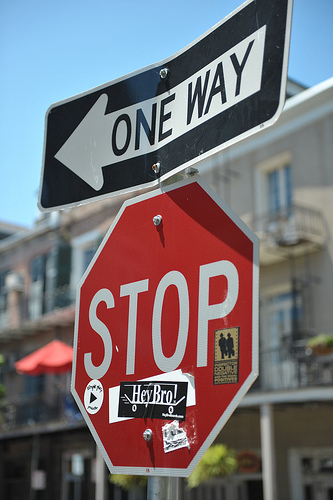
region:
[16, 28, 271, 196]
white arrow on the sign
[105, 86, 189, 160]
word on the sign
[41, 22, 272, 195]
white arrow on black background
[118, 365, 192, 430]
sticker on the sign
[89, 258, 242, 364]
white letters on sign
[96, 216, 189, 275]
light hitting the sign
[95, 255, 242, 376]
red and white sign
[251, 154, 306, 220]
window behind the sign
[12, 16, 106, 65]
blue sky above the building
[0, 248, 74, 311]
blurry background of the photo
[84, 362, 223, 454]
bumper stickers on the stop sign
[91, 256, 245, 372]
STOP written in white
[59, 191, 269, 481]
stop sign is red and white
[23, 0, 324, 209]
street sign is black and white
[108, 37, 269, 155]
ONE WAY written in black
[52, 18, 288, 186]
white arrow on street sign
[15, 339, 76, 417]
red umbrella on a balcony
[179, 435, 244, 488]
hanging flowers on the street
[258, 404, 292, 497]
white pole next to hanging basket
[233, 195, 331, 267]
balcony on the building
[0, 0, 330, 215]
Black and white one way sign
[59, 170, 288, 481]
Red and white stop sign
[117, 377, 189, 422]
Black and white sticker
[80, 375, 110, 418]
Black and white circle sticker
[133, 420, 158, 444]
silver bolt on stop sign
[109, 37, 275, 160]
Black lettering on sign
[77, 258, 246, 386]
White lettering on sign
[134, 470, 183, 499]
Silver pole to hold signs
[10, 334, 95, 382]
Red umbrella on the balcony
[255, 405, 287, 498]
White support beams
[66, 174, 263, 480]
A red and white stop sign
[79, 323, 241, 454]
Stickers on the stop sign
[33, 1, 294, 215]
A black and white sign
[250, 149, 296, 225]
A window on a building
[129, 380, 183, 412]
The saying "HeyBro!" on a sticker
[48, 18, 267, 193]
An arrow pointing left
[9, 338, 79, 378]
An open red umbrella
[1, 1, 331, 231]
A blue and clear sky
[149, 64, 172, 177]
Two nails on a sign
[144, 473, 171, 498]
Gray pole holding up signs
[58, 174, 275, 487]
THIS SIGN IS RED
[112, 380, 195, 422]
THIS STICKER IS BLACK AND WHITE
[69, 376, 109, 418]
THIS STICKER IS ROUND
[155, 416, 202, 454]
THIS STICKER IS TORN AND DAMAGED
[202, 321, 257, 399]
THIS STICKER IS BLACK AND GOLD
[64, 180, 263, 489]
THIS SIGN SAYS STOP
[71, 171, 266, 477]
THIS SIGN HAS MANY STICKERS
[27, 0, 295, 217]
THIS SIGN HAS AN ARROW ON IT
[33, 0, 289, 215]
THIS SIGN SAYS ONE WAY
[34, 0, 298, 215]
THIS SIGN IS BLACK AND WHITE